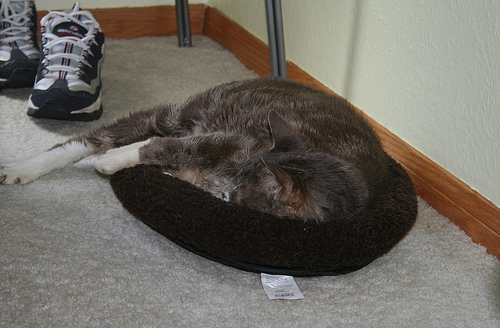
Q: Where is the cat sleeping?
A: In a pet bed.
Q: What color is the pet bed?
A: Brown.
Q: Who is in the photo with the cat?
A: No person is in the image.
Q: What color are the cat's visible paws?
A: White.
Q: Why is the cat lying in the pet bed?
A: The cat is sleeping.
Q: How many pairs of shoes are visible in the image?
A: One.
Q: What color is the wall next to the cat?
A: White.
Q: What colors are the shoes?
A: Black and white.